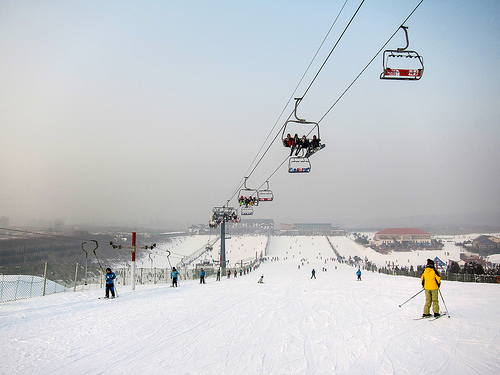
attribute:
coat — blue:
[107, 273, 115, 288]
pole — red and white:
[128, 227, 143, 294]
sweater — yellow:
[421, 268, 441, 290]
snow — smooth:
[3, 235, 498, 374]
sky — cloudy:
[439, 97, 480, 161]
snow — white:
[239, 300, 387, 370]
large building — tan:
[369, 207, 444, 259]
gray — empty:
[49, 107, 173, 164]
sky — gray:
[62, 41, 170, 99]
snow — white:
[216, 298, 393, 363]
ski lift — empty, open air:
[173, 10, 441, 265]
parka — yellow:
[417, 262, 444, 293]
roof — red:
[373, 227, 434, 234]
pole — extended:
[398, 258, 470, 332]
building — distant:
[374, 221, 437, 244]